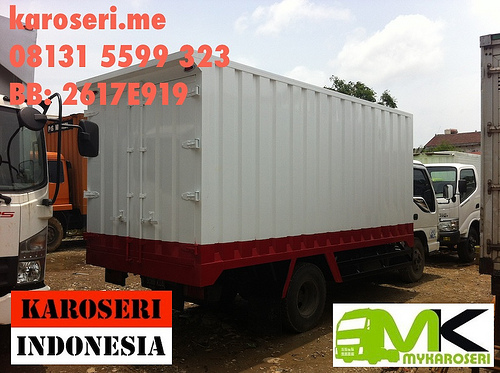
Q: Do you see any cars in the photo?
A: No, there are no cars.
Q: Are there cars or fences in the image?
A: No, there are no cars or fences.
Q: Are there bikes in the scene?
A: No, there are no bikes.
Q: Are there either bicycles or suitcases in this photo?
A: No, there are no bicycles or suitcases.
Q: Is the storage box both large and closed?
A: Yes, the storage box is large and closed.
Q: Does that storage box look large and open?
A: No, the storage box is large but closed.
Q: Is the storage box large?
A: Yes, the storage box is large.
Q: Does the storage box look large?
A: Yes, the storage box is large.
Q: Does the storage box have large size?
A: Yes, the storage box is large.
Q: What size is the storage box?
A: The storage box is large.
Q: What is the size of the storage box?
A: The storage box is large.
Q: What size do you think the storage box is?
A: The storage box is large.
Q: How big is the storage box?
A: The storage box is large.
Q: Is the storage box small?
A: No, the storage box is large.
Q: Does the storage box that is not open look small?
A: No, the storage box is large.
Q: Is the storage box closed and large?
A: Yes, the storage box is closed and large.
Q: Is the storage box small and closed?
A: No, the storage box is closed but large.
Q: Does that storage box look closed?
A: Yes, the storage box is closed.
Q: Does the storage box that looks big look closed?
A: Yes, the storage box is closed.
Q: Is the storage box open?
A: No, the storage box is closed.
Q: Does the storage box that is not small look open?
A: No, the storage box is closed.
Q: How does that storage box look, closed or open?
A: The storage box is closed.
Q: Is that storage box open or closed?
A: The storage box is closed.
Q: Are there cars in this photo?
A: No, there are no cars.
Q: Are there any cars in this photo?
A: No, there are no cars.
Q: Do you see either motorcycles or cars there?
A: No, there are no cars or motorcycles.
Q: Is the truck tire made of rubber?
A: Yes, the tire is made of rubber.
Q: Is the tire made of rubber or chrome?
A: The tire is made of rubber.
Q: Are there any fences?
A: No, there are no fences.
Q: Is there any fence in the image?
A: No, there are no fences.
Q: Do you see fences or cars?
A: No, there are no fences or cars.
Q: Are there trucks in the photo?
A: Yes, there is a truck.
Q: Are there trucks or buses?
A: Yes, there is a truck.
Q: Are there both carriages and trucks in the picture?
A: No, there is a truck but no carriages.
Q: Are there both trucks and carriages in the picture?
A: No, there is a truck but no carriages.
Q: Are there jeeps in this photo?
A: No, there are no jeeps.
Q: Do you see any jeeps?
A: No, there are no jeeps.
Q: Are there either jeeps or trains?
A: No, there are no jeeps or trains.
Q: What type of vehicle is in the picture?
A: The vehicle is a truck.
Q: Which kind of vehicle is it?
A: The vehicle is a truck.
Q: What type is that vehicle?
A: That is a truck.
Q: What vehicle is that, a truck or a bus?
A: That is a truck.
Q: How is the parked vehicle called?
A: The vehicle is a truck.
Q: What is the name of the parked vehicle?
A: The vehicle is a truck.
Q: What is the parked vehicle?
A: The vehicle is a truck.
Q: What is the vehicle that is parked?
A: The vehicle is a truck.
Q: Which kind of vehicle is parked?
A: The vehicle is a truck.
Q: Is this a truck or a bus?
A: This is a truck.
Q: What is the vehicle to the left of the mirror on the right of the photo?
A: The vehicle is a truck.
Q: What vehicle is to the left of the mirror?
A: The vehicle is a truck.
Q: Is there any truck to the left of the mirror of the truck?
A: Yes, there is a truck to the left of the mirror.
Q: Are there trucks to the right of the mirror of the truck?
A: No, the truck is to the left of the mirror.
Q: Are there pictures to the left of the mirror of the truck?
A: No, there is a truck to the left of the mirror.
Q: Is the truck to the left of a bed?
A: No, the truck is to the left of the mirror.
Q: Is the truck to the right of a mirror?
A: No, the truck is to the left of a mirror.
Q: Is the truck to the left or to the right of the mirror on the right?
A: The truck is to the left of the mirror.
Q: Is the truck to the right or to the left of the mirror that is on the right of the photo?
A: The truck is to the left of the mirror.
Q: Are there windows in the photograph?
A: Yes, there is a window.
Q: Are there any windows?
A: Yes, there is a window.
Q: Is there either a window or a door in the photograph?
A: Yes, there is a window.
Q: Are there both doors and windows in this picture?
A: Yes, there are both a window and a door.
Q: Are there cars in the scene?
A: No, there are no cars.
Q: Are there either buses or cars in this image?
A: No, there are no cars or buses.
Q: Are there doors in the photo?
A: Yes, there is a door.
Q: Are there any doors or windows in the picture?
A: Yes, there is a door.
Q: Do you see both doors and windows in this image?
A: Yes, there are both a door and windows.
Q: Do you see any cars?
A: No, there are no cars.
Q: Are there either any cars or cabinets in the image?
A: No, there are no cars or cabinets.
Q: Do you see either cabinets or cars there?
A: No, there are no cars or cabinets.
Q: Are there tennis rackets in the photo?
A: No, there are no tennis rackets.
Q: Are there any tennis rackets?
A: No, there are no tennis rackets.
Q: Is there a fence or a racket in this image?
A: No, there are no rackets or fences.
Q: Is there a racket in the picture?
A: No, there are no rackets.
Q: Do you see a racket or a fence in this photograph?
A: No, there are no rackets or fences.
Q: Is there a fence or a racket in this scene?
A: No, there are no rackets or fences.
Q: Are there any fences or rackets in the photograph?
A: No, there are no rackets or fences.